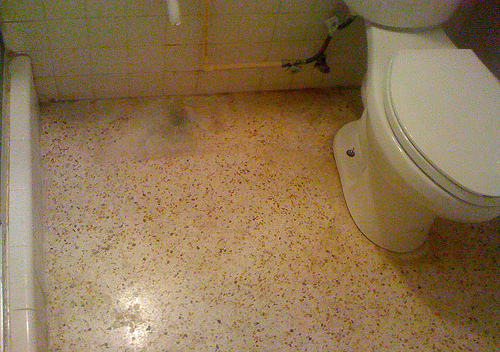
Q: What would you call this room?
A: A bathroom.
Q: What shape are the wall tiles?
A: Square.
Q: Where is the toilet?
A: On the right.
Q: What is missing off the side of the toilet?
A: The screw cover.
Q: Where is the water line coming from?
A: The wall.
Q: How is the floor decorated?
A: Colored speckles.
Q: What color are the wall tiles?
A: White.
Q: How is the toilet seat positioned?
A: Down.